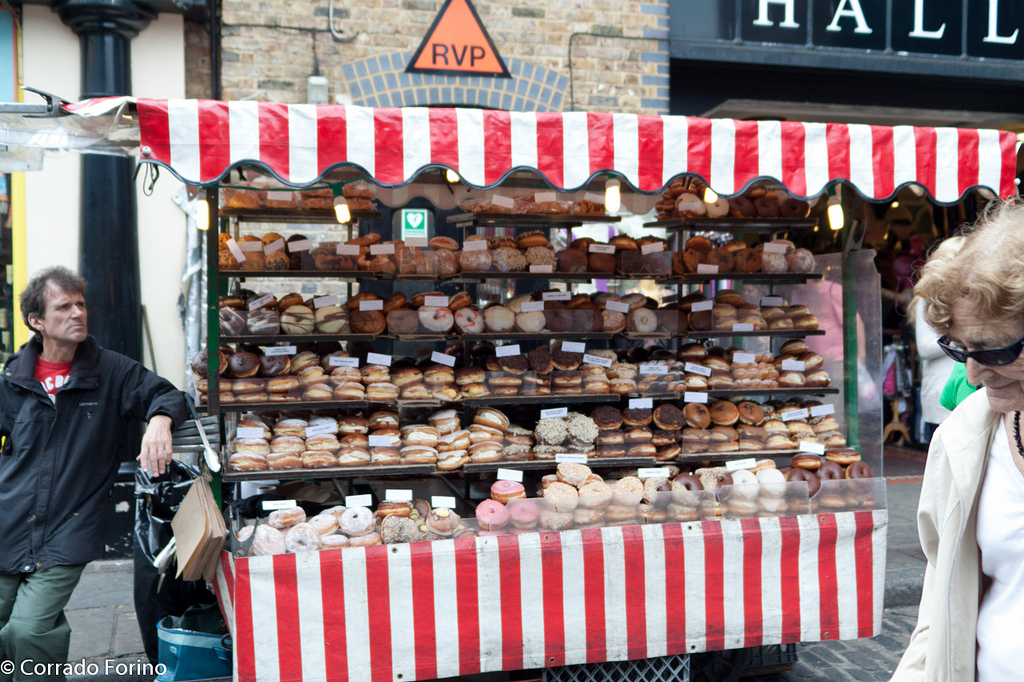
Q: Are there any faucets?
A: No, there are no faucets.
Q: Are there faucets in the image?
A: No, there are no faucets.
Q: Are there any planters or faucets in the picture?
A: No, there are no faucets or planters.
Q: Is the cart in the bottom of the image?
A: Yes, the cart is in the bottom of the image.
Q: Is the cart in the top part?
A: No, the cart is in the bottom of the image.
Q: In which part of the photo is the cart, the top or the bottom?
A: The cart is in the bottom of the image.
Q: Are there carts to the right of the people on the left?
A: Yes, there is a cart to the right of the people.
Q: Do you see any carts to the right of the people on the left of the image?
A: Yes, there is a cart to the right of the people.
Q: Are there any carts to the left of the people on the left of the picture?
A: No, the cart is to the right of the people.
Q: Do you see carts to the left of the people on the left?
A: No, the cart is to the right of the people.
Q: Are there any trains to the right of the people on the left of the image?
A: No, there is a cart to the right of the people.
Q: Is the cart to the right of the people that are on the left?
A: Yes, the cart is to the right of the people.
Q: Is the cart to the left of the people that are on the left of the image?
A: No, the cart is to the right of the people.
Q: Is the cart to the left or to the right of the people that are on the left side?
A: The cart is to the right of the people.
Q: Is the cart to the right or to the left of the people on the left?
A: The cart is to the right of the people.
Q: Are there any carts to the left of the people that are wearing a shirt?
A: Yes, there is a cart to the left of the people.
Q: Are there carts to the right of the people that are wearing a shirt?
A: No, the cart is to the left of the people.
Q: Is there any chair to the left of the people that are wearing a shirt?
A: No, there is a cart to the left of the people.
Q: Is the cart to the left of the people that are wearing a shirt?
A: Yes, the cart is to the left of the people.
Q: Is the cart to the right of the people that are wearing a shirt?
A: No, the cart is to the left of the people.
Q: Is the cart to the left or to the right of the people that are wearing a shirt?
A: The cart is to the left of the people.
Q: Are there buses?
A: No, there are no buses.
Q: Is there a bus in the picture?
A: No, there are no buses.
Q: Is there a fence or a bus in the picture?
A: No, there are no buses or fences.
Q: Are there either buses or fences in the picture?
A: No, there are no buses or fences.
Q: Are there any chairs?
A: No, there are no chairs.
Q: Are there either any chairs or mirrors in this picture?
A: No, there are no chairs or mirrors.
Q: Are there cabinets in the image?
A: No, there are no cabinets.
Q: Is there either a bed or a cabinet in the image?
A: No, there are no cabinets or beds.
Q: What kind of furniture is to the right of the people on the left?
A: The piece of furniture is a shelf.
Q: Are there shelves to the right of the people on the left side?
A: Yes, there is a shelf to the right of the people.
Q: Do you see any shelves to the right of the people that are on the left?
A: Yes, there is a shelf to the right of the people.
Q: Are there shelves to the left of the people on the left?
A: No, the shelf is to the right of the people.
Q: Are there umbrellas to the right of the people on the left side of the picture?
A: No, there is a shelf to the right of the people.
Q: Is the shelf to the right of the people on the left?
A: Yes, the shelf is to the right of the people.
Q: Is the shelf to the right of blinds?
A: No, the shelf is to the right of the people.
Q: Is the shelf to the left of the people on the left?
A: No, the shelf is to the right of the people.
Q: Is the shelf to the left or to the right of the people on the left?
A: The shelf is to the right of the people.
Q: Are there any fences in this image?
A: No, there are no fences.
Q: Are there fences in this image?
A: No, there are no fences.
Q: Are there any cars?
A: No, there are no cars.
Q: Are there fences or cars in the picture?
A: No, there are no cars or fences.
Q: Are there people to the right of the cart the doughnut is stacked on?
A: Yes, there are people to the right of the cart.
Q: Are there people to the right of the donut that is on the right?
A: Yes, there are people to the right of the doughnut.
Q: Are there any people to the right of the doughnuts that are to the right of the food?
A: Yes, there are people to the right of the donuts.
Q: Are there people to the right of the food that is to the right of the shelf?
A: Yes, there are people to the right of the food.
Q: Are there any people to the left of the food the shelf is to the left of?
A: No, the people are to the right of the food.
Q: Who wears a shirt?
A: The people wear a shirt.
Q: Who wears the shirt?
A: The people wear a shirt.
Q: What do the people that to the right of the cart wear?
A: The people wear a shirt.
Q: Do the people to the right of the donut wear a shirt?
A: Yes, the people wear a shirt.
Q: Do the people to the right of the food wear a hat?
A: No, the people wear a shirt.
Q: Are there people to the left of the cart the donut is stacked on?
A: Yes, there are people to the left of the cart.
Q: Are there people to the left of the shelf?
A: Yes, there are people to the left of the shelf.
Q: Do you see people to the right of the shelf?
A: No, the people are to the left of the shelf.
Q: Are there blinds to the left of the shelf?
A: No, there are people to the left of the shelf.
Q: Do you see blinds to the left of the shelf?
A: No, there are people to the left of the shelf.